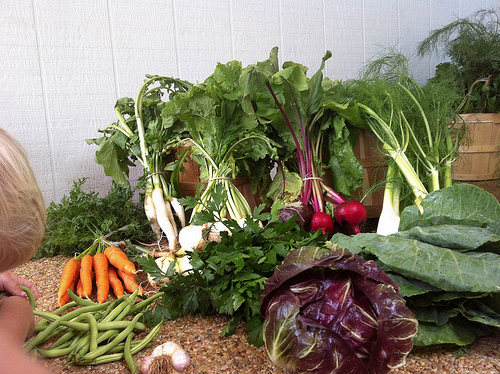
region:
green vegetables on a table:
[0, 1, 497, 371]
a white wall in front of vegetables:
[6, 0, 478, 221]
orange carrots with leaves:
[38, 183, 149, 299]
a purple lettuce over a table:
[258, 232, 421, 372]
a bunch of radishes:
[281, 100, 368, 235]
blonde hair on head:
[1, 125, 57, 288]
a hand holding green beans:
[1, 268, 88, 368]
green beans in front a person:
[1, 273, 162, 372]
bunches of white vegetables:
[132, 160, 255, 270]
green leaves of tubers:
[111, 58, 471, 165]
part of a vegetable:
[403, 156, 418, 168]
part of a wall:
[91, 129, 116, 169]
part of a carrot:
[126, 296, 141, 319]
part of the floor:
[216, 341, 228, 358]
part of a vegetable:
[336, 224, 345, 234]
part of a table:
[230, 353, 244, 368]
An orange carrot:
[104, 246, 140, 274]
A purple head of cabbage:
[260, 241, 420, 373]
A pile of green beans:
[14, 281, 167, 371]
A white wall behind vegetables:
[1, 0, 499, 231]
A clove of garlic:
[139, 340, 193, 371]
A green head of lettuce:
[329, 181, 499, 346]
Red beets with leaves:
[239, 49, 366, 240]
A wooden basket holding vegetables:
[175, 139, 278, 225]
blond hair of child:
[1, 125, 45, 274]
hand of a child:
[0, 269, 40, 299]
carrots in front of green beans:
[62, 234, 148, 296]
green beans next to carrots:
[39, 288, 163, 370]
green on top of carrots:
[63, 173, 126, 245]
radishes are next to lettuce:
[293, 168, 371, 247]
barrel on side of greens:
[438, 71, 498, 184]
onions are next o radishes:
[193, 183, 274, 246]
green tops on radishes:
[218, 56, 360, 152]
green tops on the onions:
[173, 71, 251, 171]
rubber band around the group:
[196, 164, 258, 200]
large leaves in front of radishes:
[377, 212, 497, 370]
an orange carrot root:
[56, 258, 76, 298]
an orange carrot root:
[81, 252, 91, 296]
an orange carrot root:
[92, 251, 108, 301]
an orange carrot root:
[103, 243, 138, 274]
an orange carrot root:
[107, 264, 124, 298]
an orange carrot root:
[114, 265, 145, 295]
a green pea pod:
[76, 312, 140, 361]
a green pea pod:
[124, 329, 137, 369]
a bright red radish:
[332, 198, 368, 236]